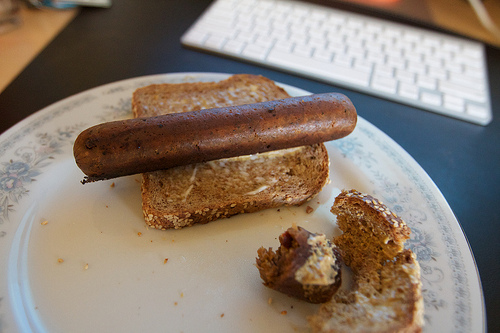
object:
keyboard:
[178, 0, 492, 127]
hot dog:
[73, 91, 358, 181]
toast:
[131, 72, 330, 230]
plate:
[0, 71, 489, 332]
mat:
[0, 0, 499, 331]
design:
[329, 120, 474, 332]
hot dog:
[255, 225, 342, 305]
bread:
[306, 187, 425, 332]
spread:
[294, 231, 340, 285]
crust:
[333, 188, 409, 230]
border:
[0, 5, 83, 94]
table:
[0, 0, 500, 332]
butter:
[321, 290, 411, 332]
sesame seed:
[384, 209, 391, 215]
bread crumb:
[304, 204, 315, 214]